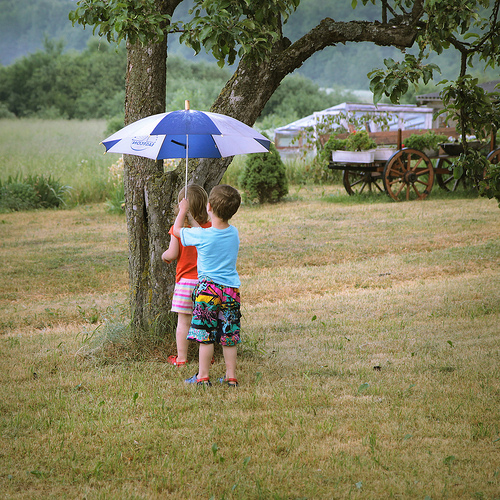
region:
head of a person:
[200, 183, 248, 237]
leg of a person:
[183, 303, 221, 388]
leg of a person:
[207, 308, 254, 385]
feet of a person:
[187, 361, 227, 408]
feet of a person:
[226, 363, 248, 391]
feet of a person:
[165, 345, 202, 373]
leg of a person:
[165, 312, 197, 350]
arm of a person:
[179, 215, 201, 255]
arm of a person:
[163, 222, 188, 260]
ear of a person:
[206, 195, 214, 210]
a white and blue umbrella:
[94, 96, 226, 233]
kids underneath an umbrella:
[91, 108, 306, 327]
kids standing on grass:
[102, 93, 365, 483]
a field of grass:
[304, 368, 417, 487]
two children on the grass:
[162, 111, 344, 436]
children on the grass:
[121, 150, 383, 441]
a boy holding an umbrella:
[82, 53, 284, 435]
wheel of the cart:
[381, 145, 435, 204]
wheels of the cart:
[337, 145, 498, 204]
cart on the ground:
[317, 117, 499, 208]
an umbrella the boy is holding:
[96, 95, 277, 209]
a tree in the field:
[61, 1, 491, 364]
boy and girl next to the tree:
[155, 177, 252, 397]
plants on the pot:
[320, 127, 380, 169]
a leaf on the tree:
[369, 79, 389, 112]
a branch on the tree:
[297, 2, 409, 67]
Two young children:
[155, 157, 266, 402]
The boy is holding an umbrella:
[104, 101, 293, 393]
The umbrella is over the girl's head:
[92, 103, 289, 387]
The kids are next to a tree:
[152, 163, 284, 405]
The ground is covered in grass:
[12, 323, 487, 491]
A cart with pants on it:
[330, 120, 495, 210]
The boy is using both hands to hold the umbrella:
[175, 161, 265, 398]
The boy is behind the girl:
[112, 93, 300, 388]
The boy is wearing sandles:
[170, 367, 261, 393]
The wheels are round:
[380, 145, 475, 202]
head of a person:
[202, 182, 257, 229]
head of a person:
[169, 179, 211, 236]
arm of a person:
[165, 215, 203, 249]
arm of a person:
[156, 236, 184, 277]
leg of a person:
[152, 313, 199, 377]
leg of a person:
[189, 328, 219, 388]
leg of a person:
[222, 322, 260, 376]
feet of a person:
[159, 342, 196, 369]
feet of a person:
[177, 375, 219, 416]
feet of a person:
[213, 365, 255, 397]